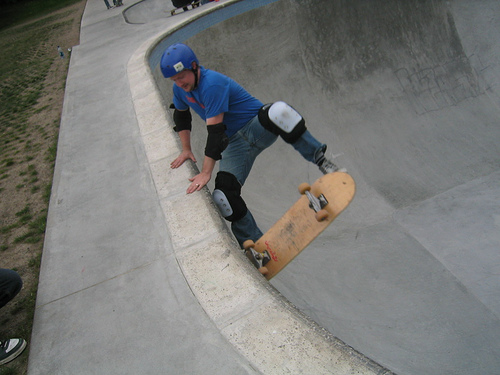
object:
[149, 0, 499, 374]
ramp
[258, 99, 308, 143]
pads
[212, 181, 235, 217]
knee cap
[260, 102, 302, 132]
knee cap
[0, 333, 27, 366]
shoe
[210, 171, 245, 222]
pads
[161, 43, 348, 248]
man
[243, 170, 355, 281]
skateboard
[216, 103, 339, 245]
jeans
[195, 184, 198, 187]
ring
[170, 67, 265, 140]
shirt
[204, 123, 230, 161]
elbow pads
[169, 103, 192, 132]
elbow pads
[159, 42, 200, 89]
helmet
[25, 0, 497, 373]
pavement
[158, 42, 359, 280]
skating ring